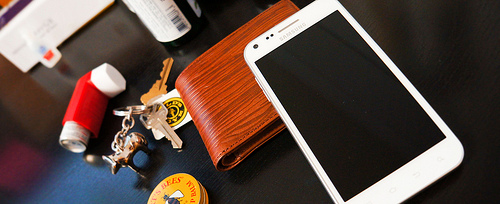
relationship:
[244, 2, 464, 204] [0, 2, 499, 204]
cellphone on table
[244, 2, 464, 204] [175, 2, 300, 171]
cellphone on wallet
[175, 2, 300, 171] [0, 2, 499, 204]
wallet on desk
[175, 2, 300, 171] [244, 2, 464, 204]
wallet underneath cellphone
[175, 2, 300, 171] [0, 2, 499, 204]
wallet on table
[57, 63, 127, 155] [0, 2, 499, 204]
inhaler on table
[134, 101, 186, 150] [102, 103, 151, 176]
golds on chain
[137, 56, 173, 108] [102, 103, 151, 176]
key on chain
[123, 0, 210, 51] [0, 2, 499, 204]
bottle on table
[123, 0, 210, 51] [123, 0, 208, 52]
bottle of medication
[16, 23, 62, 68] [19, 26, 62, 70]
drops for eyes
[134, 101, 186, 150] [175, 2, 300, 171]
golds by wallet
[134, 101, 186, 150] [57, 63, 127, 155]
golds by inhaler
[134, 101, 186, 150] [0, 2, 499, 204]
golds on table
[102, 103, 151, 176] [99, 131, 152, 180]
key chain has animal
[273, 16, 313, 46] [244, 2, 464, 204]
samsung brand cellphone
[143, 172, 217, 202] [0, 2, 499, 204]
container on table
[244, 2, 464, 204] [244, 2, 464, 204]
white samsung cellphone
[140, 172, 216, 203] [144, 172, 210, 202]
balm lip balm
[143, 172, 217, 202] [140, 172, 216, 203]
container says balm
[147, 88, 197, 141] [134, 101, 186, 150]
tag by golds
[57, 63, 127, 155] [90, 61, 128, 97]
inhaler with cap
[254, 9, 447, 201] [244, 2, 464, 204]
screen of cellphone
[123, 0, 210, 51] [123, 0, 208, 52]
bottle of medicine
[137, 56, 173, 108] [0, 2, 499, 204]
key on table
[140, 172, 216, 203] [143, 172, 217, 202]
balm balm container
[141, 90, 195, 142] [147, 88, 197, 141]
golds gym tag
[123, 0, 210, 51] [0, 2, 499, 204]
bottle on desk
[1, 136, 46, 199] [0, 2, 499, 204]
reflection on table